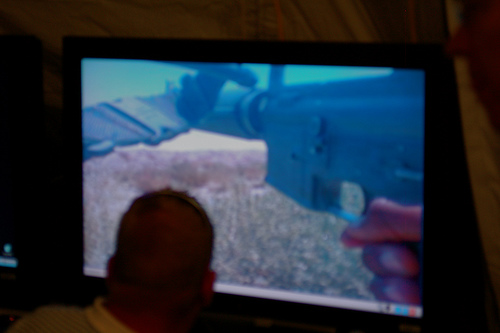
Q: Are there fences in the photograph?
A: No, there are no fences.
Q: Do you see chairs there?
A: No, there are no chairs.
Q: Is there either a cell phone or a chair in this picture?
A: No, there are no chairs or cell phones.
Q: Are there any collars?
A: Yes, there is a collar.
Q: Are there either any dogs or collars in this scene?
A: Yes, there is a collar.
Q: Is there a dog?
A: No, there are no dogs.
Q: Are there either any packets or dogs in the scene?
A: No, there are no dogs or packets.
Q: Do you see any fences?
A: No, there are no fences.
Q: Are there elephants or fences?
A: No, there are no fences or elephants.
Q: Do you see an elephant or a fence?
A: No, there are no fences or elephants.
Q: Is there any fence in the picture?
A: No, there are no fences.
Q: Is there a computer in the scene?
A: Yes, there is a computer.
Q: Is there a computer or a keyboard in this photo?
A: Yes, there is a computer.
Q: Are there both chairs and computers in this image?
A: No, there is a computer but no chairs.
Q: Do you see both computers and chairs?
A: No, there is a computer but no chairs.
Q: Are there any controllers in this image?
A: No, there are no controllers.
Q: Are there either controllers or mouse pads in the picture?
A: No, there are no controllers or mouse pads.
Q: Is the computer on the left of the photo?
A: Yes, the computer is on the left of the image.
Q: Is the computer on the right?
A: No, the computer is on the left of the image.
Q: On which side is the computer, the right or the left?
A: The computer is on the left of the image.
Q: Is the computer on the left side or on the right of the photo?
A: The computer is on the left of the image.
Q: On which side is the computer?
A: The computer is on the left of the image.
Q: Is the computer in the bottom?
A: Yes, the computer is in the bottom of the image.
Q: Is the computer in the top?
A: No, the computer is in the bottom of the image.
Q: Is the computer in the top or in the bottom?
A: The computer is in the bottom of the image.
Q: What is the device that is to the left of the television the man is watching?
A: The device is a computer.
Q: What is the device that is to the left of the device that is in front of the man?
A: The device is a computer.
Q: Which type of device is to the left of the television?
A: The device is a computer.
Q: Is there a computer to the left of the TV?
A: Yes, there is a computer to the left of the TV.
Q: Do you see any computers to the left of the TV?
A: Yes, there is a computer to the left of the TV.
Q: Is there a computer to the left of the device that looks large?
A: Yes, there is a computer to the left of the TV.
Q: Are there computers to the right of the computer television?
A: No, the computer is to the left of the TV.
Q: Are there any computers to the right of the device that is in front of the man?
A: No, the computer is to the left of the TV.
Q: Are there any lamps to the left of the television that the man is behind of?
A: No, there is a computer to the left of the television.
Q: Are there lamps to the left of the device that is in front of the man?
A: No, there is a computer to the left of the television.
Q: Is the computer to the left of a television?
A: Yes, the computer is to the left of a television.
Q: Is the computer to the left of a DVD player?
A: No, the computer is to the left of a television.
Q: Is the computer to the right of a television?
A: No, the computer is to the left of a television.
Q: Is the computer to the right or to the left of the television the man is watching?
A: The computer is to the left of the TV.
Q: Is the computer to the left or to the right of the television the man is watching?
A: The computer is to the left of the TV.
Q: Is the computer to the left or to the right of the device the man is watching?
A: The computer is to the left of the TV.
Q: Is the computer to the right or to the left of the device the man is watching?
A: The computer is to the left of the TV.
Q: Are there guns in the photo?
A: Yes, there is a gun.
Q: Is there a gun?
A: Yes, there is a gun.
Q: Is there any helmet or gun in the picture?
A: Yes, there is a gun.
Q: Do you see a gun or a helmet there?
A: Yes, there is a gun.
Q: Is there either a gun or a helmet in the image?
A: Yes, there is a gun.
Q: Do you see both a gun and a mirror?
A: No, there is a gun but no mirrors.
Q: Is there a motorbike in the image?
A: No, there are no motorcycles.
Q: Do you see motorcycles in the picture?
A: No, there are no motorcycles.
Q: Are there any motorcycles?
A: No, there are no motorcycles.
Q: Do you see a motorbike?
A: No, there are no motorcycles.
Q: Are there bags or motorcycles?
A: No, there are no motorcycles or bags.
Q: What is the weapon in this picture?
A: The weapon is a gun.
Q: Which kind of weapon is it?
A: The weapon is a gun.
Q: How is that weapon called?
A: That is a gun.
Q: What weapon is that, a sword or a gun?
A: That is a gun.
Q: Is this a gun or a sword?
A: This is a gun.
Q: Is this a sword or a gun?
A: This is a gun.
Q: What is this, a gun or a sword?
A: This is a gun.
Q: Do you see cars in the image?
A: No, there are no cars.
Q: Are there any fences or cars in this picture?
A: No, there are no cars or fences.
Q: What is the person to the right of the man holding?
A: The person is holding the gun.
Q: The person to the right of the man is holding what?
A: The person is holding the gun.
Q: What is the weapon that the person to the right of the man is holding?
A: The weapon is a gun.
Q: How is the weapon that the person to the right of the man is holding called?
A: The weapon is a gun.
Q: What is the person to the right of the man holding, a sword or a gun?
A: The person is holding a gun.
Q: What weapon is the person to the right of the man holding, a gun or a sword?
A: The person is holding a gun.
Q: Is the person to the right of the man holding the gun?
A: Yes, the person is holding the gun.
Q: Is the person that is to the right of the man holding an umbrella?
A: No, the person is holding the gun.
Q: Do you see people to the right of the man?
A: Yes, there is a person to the right of the man.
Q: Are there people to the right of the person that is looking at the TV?
A: Yes, there is a person to the right of the man.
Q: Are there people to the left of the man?
A: No, the person is to the right of the man.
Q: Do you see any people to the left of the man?
A: No, the person is to the right of the man.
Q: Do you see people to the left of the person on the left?
A: No, the person is to the right of the man.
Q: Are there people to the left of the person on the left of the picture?
A: No, the person is to the right of the man.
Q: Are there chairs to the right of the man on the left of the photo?
A: No, there is a person to the right of the man.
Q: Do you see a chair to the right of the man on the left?
A: No, there is a person to the right of the man.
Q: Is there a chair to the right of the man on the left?
A: No, there is a person to the right of the man.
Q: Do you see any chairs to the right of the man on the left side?
A: No, there is a person to the right of the man.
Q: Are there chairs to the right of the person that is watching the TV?
A: No, there is a person to the right of the man.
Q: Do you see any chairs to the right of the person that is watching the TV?
A: No, there is a person to the right of the man.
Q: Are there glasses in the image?
A: No, there are no glasses.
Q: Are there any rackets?
A: No, there are no rackets.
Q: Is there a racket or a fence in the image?
A: No, there are no rackets or fences.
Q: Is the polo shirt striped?
A: Yes, the polo shirt is striped.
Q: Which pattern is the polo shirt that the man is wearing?
A: The polo shirt is striped.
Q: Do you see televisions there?
A: Yes, there is a television.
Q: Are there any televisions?
A: Yes, there is a television.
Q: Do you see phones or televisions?
A: Yes, there is a television.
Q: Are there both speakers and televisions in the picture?
A: No, there is a television but no speakers.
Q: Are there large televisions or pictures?
A: Yes, there is a large television.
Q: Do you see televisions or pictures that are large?
A: Yes, the television is large.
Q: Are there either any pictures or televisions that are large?
A: Yes, the television is large.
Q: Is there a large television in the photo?
A: Yes, there is a large television.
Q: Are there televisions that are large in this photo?
A: Yes, there is a large television.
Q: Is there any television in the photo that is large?
A: Yes, there is a television that is large.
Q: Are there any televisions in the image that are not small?
A: Yes, there is a large television.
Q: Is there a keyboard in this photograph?
A: No, there are no keyboards.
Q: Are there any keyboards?
A: No, there are no keyboards.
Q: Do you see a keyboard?
A: No, there are no keyboards.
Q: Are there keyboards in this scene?
A: No, there are no keyboards.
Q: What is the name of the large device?
A: The device is a television.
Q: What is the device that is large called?
A: The device is a television.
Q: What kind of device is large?
A: The device is a television.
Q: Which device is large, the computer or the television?
A: The television is large.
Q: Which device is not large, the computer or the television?
A: The computer is not large.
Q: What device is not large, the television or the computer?
A: The computer is not large.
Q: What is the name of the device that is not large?
A: The device is a computer.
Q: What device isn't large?
A: The device is a computer.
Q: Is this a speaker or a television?
A: This is a television.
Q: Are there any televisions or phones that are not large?
A: No, there is a television but it is large.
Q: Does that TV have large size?
A: Yes, the TV is large.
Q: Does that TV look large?
A: Yes, the TV is large.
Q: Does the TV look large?
A: Yes, the TV is large.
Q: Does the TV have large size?
A: Yes, the TV is large.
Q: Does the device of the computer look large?
A: Yes, the TV is large.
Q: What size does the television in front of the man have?
A: The TV has large size.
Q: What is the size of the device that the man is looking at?
A: The TV is large.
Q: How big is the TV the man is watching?
A: The television is large.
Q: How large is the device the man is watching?
A: The television is large.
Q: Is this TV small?
A: No, the TV is large.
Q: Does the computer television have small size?
A: No, the TV is large.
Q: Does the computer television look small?
A: No, the TV is large.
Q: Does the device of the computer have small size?
A: No, the TV is large.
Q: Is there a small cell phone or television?
A: No, there is a television but it is large.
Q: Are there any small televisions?
A: No, there is a television but it is large.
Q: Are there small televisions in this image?
A: No, there is a television but it is large.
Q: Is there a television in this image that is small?
A: No, there is a television but it is large.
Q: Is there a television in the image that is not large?
A: No, there is a television but it is large.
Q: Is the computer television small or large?
A: The TV is large.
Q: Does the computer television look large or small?
A: The TV is large.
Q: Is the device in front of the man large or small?
A: The TV is large.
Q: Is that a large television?
A: Yes, that is a large television.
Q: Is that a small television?
A: No, that is a large television.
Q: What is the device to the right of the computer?
A: The device is a television.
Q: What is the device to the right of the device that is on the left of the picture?
A: The device is a television.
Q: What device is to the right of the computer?
A: The device is a television.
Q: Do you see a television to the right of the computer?
A: Yes, there is a television to the right of the computer.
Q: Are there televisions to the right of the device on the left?
A: Yes, there is a television to the right of the computer.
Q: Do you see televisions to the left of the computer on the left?
A: No, the television is to the right of the computer.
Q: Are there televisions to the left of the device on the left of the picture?
A: No, the television is to the right of the computer.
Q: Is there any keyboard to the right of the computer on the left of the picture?
A: No, there is a television to the right of the computer.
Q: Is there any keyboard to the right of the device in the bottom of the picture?
A: No, there is a television to the right of the computer.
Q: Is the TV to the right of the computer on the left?
A: Yes, the TV is to the right of the computer.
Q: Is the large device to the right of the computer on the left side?
A: Yes, the TV is to the right of the computer.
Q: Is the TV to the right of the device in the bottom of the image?
A: Yes, the TV is to the right of the computer.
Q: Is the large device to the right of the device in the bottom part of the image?
A: Yes, the TV is to the right of the computer.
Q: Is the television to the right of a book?
A: No, the television is to the right of the computer.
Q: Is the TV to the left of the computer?
A: No, the TV is to the right of the computer.